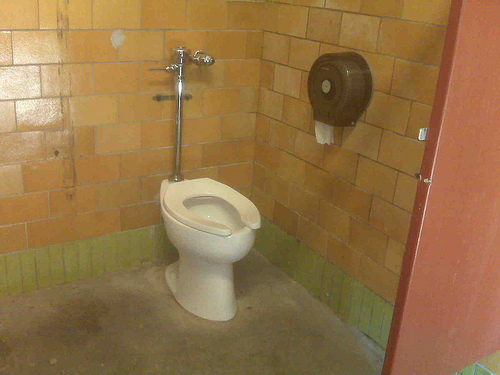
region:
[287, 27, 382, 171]
a toilet paper dispenser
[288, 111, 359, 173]
the toilet paper is white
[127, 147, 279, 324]
the toilet is white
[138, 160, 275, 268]
the toilet is clean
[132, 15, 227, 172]
the pipe is silver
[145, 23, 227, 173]
the pole is attached to the wall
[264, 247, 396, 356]
the bottom of the wall is green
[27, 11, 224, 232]
the wall is made of tiles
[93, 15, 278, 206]
the wall is tan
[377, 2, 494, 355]
the stall door is brick red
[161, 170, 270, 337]
this is a toilet sink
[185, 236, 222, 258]
the sink is white in color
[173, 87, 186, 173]
this is a pipe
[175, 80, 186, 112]
the pipe is shinny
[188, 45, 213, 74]
this is the tap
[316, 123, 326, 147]
this is a tissue paper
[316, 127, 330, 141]
the tissue paper is white in color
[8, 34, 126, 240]
this is the wall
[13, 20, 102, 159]
the wall is brown in color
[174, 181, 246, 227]
the sink is uncovered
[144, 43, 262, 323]
a white porcelain public toilet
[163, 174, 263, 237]
a white plastic toilet seat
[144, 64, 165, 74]
a chrome flush handle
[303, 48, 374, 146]
a toilet paper dispenser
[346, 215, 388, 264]
a brown rectangle wall tile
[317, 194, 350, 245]
a brown rectangle wall tile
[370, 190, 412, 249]
a brown rectangle wall tile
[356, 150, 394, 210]
a brown rectangle wall tile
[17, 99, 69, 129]
a brown rectangle wall tile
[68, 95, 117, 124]
a brown rectangle wall tile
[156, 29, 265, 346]
Toilet sitting in corner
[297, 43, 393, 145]
Toilet paper holder on wall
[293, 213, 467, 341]
Tiles on the wall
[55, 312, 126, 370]
The floor is concrete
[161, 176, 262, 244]
Toilet seat is down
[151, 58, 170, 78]
Handle on the toilet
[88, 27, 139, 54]
Stain on the wall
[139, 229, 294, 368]
Base on the toilet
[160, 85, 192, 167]
Metal pole on the toilet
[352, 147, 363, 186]
Grout on the wall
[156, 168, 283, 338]
A white toilet seat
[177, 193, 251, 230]
A white toilet plate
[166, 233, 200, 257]
A white tiolet pan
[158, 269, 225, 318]
A flat plate kit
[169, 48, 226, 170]
A metalic water pump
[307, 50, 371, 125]
A black tissue holder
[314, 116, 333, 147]
A white tissue paper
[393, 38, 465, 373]
A red toilet door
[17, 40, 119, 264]
A brick toilet wall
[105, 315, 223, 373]
A brown toilet floor